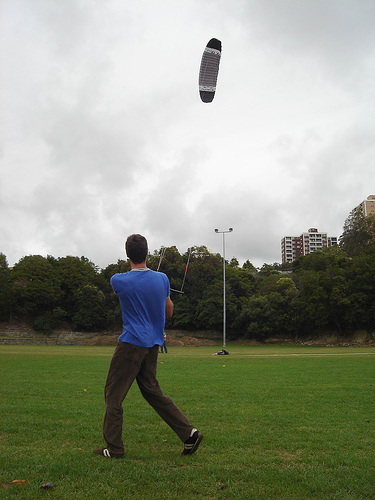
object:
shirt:
[108, 267, 172, 346]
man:
[93, 233, 204, 460]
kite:
[198, 36, 223, 104]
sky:
[0, 0, 374, 269]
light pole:
[214, 226, 236, 356]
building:
[280, 226, 339, 269]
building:
[346, 192, 374, 229]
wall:
[1, 325, 103, 347]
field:
[0, 343, 375, 498]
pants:
[101, 341, 192, 453]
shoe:
[179, 426, 202, 458]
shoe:
[92, 445, 126, 460]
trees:
[0, 215, 374, 338]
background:
[1, 135, 374, 285]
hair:
[126, 233, 149, 265]